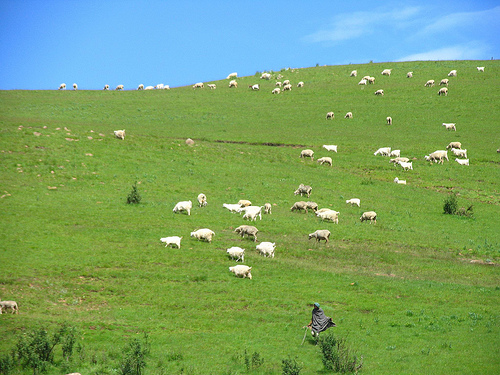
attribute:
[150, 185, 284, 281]
sheep — many, white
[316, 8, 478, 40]
clouds — thin, white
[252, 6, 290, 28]
sky — bright, blue, clear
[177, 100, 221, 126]
hill — grassy, green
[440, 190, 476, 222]
bush — green, large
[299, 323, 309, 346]
cane — white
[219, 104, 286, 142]
field — large, green, grassy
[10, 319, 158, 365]
shrubs — green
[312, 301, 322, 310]
hat — green